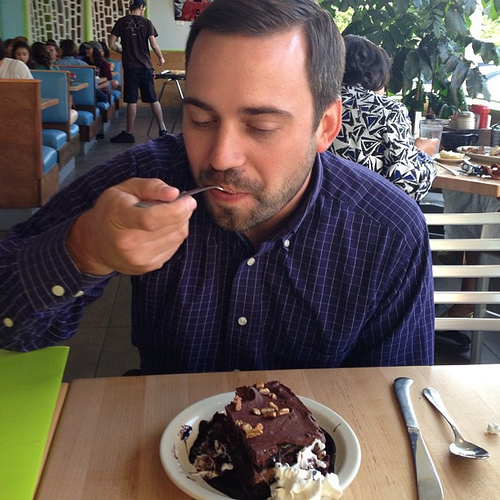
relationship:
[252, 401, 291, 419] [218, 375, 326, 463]
nuts on brownie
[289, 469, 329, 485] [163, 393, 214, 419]
whipped cream on plate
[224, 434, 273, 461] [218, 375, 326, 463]
frosting on brownie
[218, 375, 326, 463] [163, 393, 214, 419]
brownie on plate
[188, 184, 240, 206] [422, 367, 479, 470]
fork next to spoon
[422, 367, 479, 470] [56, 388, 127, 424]
spoon on table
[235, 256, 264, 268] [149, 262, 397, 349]
buttons on shirt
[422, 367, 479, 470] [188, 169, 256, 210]
spoon in mouth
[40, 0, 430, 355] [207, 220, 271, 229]
man has beard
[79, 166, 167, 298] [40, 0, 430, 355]
hand of man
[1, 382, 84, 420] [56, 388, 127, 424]
object on table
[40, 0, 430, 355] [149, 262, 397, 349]
man wearing shirt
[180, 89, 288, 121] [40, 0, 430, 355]
eyebrows of man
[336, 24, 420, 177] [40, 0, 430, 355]
woman behind man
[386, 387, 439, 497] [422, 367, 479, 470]
knife and spoon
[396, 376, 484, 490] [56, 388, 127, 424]
utensils on table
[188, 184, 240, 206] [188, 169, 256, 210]
fork in mouth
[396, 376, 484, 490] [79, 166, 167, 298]
utensils in hand